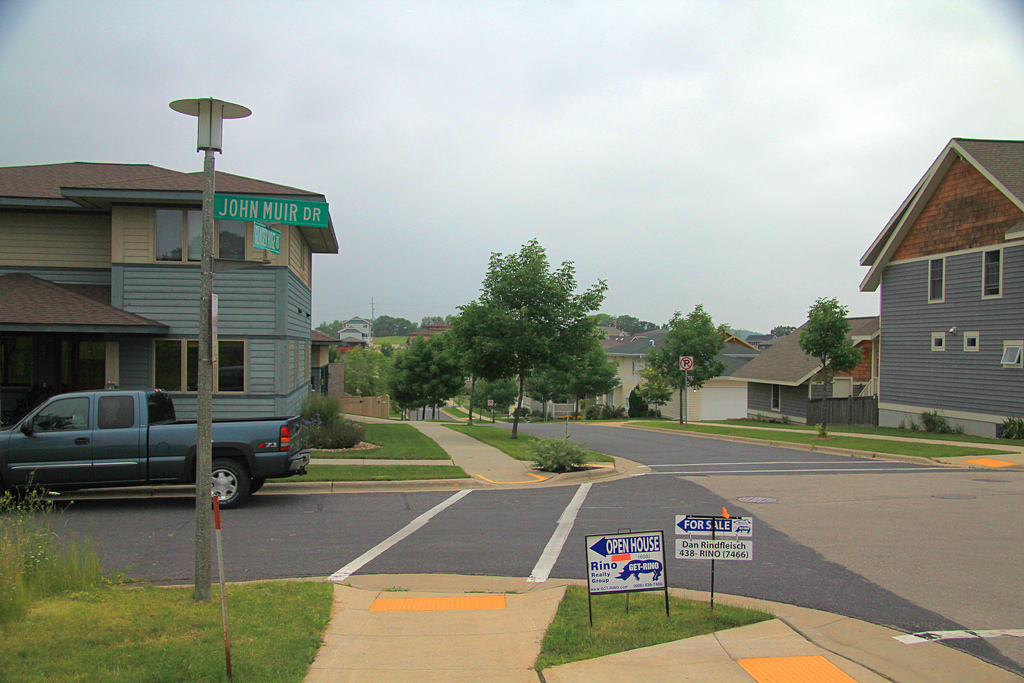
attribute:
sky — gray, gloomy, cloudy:
[247, 5, 965, 319]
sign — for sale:
[619, 499, 818, 633]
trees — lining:
[427, 279, 652, 431]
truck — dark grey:
[45, 368, 333, 535]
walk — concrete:
[412, 402, 555, 526]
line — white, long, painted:
[530, 471, 610, 575]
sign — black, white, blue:
[580, 523, 672, 601]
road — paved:
[477, 411, 992, 654]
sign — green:
[214, 189, 327, 222]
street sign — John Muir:
[211, 191, 328, 233]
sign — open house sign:
[587, 526, 672, 620]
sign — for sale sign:
[673, 513, 756, 607]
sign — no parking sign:
[675, 355, 699, 422]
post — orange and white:
[205, 494, 238, 680]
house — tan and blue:
[3, 161, 338, 430]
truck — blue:
[6, 386, 307, 507]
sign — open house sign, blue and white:
[583, 526, 674, 626]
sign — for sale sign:
[671, 507, 754, 564]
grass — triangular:
[533, 580, 775, 667]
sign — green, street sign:
[217, 189, 332, 229]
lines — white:
[326, 478, 590, 587]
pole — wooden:
[200, 152, 214, 591]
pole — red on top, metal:
[211, 491, 235, 680]